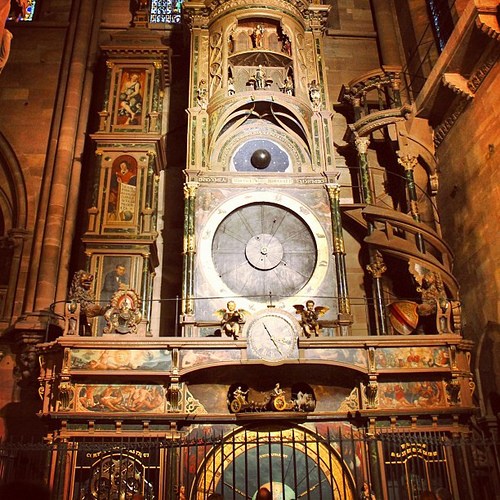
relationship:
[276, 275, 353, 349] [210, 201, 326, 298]
angel sitting by a clock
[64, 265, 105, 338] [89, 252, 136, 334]
lion at bottom of picture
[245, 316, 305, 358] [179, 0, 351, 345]
clock in tower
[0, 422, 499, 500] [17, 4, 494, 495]
gate protects tower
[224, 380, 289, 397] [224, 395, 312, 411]
people ride in chariots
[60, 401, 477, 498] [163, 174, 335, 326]
gate in front of clock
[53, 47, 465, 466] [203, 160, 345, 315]
painting on wall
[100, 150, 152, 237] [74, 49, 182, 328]
painting on wall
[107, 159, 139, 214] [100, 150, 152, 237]
man on painting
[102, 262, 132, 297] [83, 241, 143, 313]
man on window